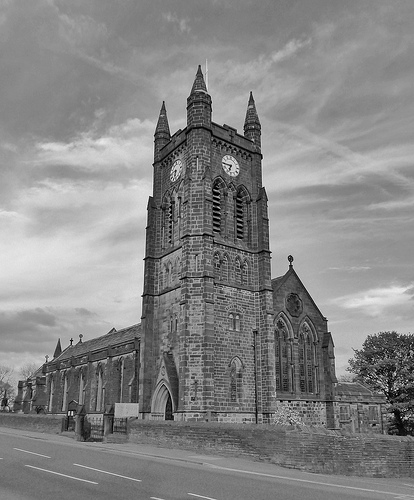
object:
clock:
[219, 152, 241, 179]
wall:
[210, 125, 259, 422]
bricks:
[210, 286, 229, 315]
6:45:
[223, 154, 243, 176]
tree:
[345, 331, 413, 435]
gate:
[79, 414, 102, 439]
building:
[16, 64, 384, 446]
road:
[1, 427, 413, 498]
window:
[208, 175, 227, 241]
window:
[235, 186, 252, 244]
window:
[160, 190, 176, 248]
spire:
[188, 65, 212, 122]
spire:
[245, 91, 263, 145]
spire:
[152, 99, 168, 157]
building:
[272, 251, 327, 427]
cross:
[226, 132, 235, 144]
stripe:
[25, 462, 99, 492]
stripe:
[74, 461, 143, 484]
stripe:
[12, 445, 54, 461]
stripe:
[185, 490, 223, 499]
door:
[160, 393, 176, 419]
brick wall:
[0, 414, 413, 477]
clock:
[169, 160, 185, 181]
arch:
[147, 351, 188, 425]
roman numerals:
[225, 157, 230, 162]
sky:
[1, 0, 413, 325]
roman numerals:
[177, 164, 183, 169]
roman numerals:
[234, 171, 239, 175]